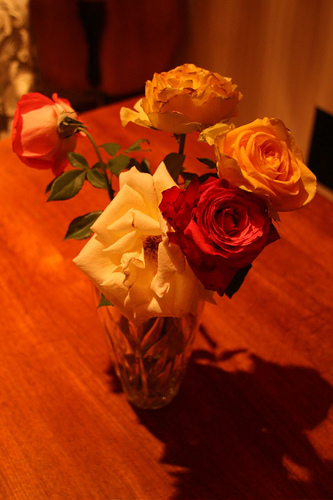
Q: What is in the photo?
A: Flower and vase and table.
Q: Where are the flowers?
A: In the vase.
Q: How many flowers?
A: 5.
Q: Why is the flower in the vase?
A: Display.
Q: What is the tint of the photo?
A: Warm tint.